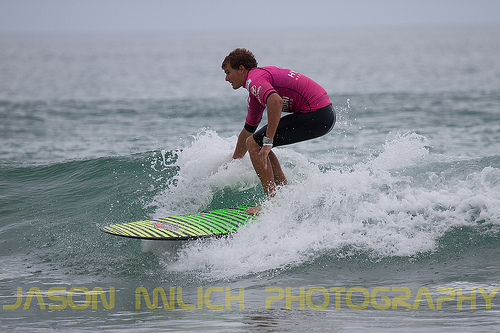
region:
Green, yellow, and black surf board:
[103, 207, 260, 238]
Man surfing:
[219, 49, 335, 216]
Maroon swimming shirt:
[241, 68, 331, 125]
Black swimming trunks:
[252, 105, 339, 150]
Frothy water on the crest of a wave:
[155, 132, 498, 279]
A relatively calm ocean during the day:
[0, 31, 498, 329]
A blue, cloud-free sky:
[0, 0, 498, 23]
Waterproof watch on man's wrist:
[260, 135, 270, 140]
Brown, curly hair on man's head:
[220, 45, 255, 65]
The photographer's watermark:
[4, 287, 497, 311]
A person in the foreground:
[183, 39, 358, 219]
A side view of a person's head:
[211, 42, 265, 102]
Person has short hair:
[210, 43, 265, 93]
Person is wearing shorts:
[242, 95, 347, 165]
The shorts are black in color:
[245, 102, 344, 169]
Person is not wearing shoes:
[236, 181, 279, 225]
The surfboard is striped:
[85, 195, 263, 253]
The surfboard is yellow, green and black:
[94, 197, 256, 268]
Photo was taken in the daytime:
[2, 7, 499, 329]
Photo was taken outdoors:
[2, 4, 498, 331]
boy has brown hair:
[210, 47, 252, 77]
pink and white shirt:
[244, 67, 317, 147]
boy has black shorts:
[263, 97, 319, 138]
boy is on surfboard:
[101, 57, 320, 246]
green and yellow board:
[103, 193, 245, 239]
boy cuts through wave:
[107, 202, 303, 284]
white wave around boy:
[206, 169, 397, 325]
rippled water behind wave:
[341, 42, 426, 124]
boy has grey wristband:
[257, 127, 276, 157]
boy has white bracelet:
[258, 139, 273, 151]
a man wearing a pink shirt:
[213, 48, 328, 200]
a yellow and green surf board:
[98, 191, 262, 245]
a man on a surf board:
[91, 47, 347, 247]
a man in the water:
[220, 51, 328, 231]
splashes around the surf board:
[263, 173, 306, 211]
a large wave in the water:
[49, 143, 283, 238]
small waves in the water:
[16, 53, 137, 135]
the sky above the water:
[9, 5, 484, 23]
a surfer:
[116, 42, 361, 255]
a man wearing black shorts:
[219, 45, 331, 191]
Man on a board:
[93, 190, 271, 247]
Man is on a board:
[97, 192, 282, 244]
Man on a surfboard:
[97, 188, 287, 250]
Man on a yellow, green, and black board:
[95, 191, 294, 245]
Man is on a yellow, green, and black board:
[91, 195, 287, 246]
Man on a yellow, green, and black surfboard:
[100, 200, 280, 245]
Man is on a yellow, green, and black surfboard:
[91, 198, 272, 243]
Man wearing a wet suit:
[238, 62, 344, 156]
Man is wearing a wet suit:
[238, 61, 341, 153]